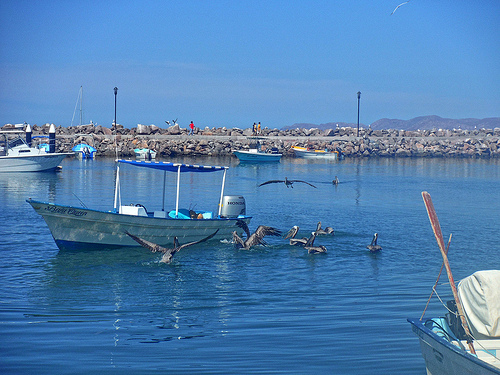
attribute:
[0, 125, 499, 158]
beach — rocky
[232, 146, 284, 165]
boat — blue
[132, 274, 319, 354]
ripples — dark, line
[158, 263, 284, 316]
water — calm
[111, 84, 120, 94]
street lamp — tall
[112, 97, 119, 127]
pole — black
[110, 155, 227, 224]
canopy — striped, blued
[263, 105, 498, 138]
mountain — brown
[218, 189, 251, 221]
motor — honda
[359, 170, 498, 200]
water — calm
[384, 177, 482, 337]
oar — wooden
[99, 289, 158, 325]
water — calm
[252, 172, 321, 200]
bird — long span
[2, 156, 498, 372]
water — calm